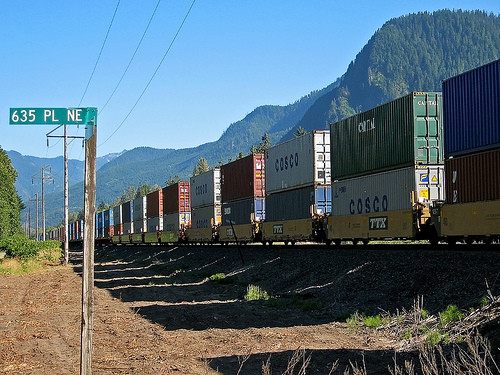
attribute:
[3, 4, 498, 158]
sky —  clear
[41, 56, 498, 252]
train cars —  train , behind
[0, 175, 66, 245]
poles — utility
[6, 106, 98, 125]
street sign — street 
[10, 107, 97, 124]
sign — street 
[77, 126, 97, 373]
pole — metal 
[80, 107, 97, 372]
pole — metal 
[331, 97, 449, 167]
rail car — green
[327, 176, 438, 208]
rail car — grey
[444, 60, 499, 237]
train car — train 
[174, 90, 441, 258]
train — double decker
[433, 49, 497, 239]
train car — train  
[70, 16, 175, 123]
lines — power 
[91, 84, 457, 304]
train — cars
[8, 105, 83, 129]
lettering — green and white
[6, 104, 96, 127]
sign — green street 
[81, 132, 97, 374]
pole — metal 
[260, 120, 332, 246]
train cars — double decker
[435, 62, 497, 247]
car — double decker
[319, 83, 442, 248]
car — double decker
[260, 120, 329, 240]
car — double decker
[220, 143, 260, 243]
car — double decker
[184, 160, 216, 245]
car — double decker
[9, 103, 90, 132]
sign — green, white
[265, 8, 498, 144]
mountain — distant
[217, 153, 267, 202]
train car — red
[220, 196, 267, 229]
train car — blue